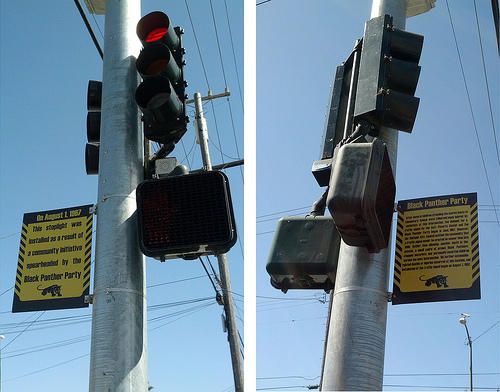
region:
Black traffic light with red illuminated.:
[133, 12, 186, 146]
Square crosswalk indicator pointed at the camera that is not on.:
[133, 172, 235, 259]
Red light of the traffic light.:
[143, 26, 168, 40]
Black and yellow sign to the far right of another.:
[390, 193, 481, 303]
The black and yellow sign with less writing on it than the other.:
[11, 203, 96, 309]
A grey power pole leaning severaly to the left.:
[183, 87, 248, 390]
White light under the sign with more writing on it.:
[459, 314, 469, 326]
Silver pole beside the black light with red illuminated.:
[87, 0, 147, 390]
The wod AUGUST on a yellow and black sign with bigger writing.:
[43, 210, 62, 220]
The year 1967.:
[68, 205, 83, 217]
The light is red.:
[135, 13, 171, 40]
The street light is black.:
[137, 13, 186, 140]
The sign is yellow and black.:
[394, 189, 478, 299]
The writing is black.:
[398, 209, 473, 266]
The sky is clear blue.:
[17, 7, 489, 381]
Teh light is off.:
[133, 171, 242, 251]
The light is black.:
[132, 173, 240, 263]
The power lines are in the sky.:
[71, 3, 248, 342]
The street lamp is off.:
[446, 310, 471, 324]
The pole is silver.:
[94, 2, 149, 391]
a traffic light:
[125, 13, 202, 143]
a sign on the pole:
[24, 206, 84, 306]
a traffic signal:
[140, 175, 238, 250]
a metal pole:
[336, 278, 378, 389]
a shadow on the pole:
[90, 237, 145, 378]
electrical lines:
[185, 25, 240, 70]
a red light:
[132, 15, 169, 42]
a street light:
[450, 306, 475, 343]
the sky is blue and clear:
[257, 15, 313, 115]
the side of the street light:
[358, 11, 403, 112]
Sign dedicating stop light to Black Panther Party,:
[10, 202, 97, 312]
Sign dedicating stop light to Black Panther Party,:
[383, 188, 485, 308]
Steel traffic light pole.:
[81, 0, 156, 390]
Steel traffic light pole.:
[315, 0, 430, 390]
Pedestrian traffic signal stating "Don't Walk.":
[133, 161, 238, 261]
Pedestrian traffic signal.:
[325, 135, 400, 255]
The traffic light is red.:
[132, 8, 192, 145]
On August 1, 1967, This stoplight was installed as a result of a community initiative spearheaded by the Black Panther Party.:
[9, 201, 95, 313]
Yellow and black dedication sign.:
[390, 192, 485, 306]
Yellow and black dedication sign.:
[9, 199, 96, 311]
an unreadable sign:
[398, 195, 479, 300]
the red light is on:
[139, 11, 168, 42]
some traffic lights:
[91, 20, 446, 160]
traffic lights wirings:
[192, 0, 239, 152]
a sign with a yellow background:
[18, 214, 95, 306]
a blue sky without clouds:
[3, 11, 76, 176]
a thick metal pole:
[92, 146, 146, 390]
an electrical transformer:
[194, 113, 210, 145]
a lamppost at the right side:
[456, 310, 476, 388]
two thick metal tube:
[91, 270, 388, 387]